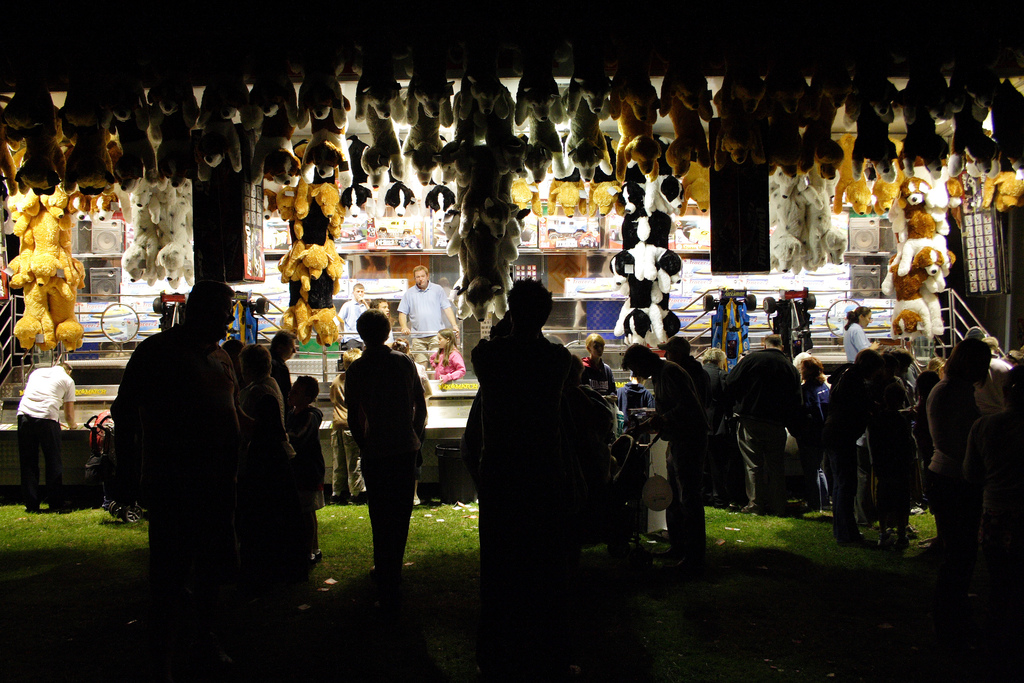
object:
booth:
[3, 9, 989, 502]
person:
[339, 309, 434, 582]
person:
[463, 264, 589, 666]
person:
[614, 340, 718, 570]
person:
[109, 268, 256, 677]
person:
[855, 346, 920, 548]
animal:
[0, 183, 92, 357]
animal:
[269, 167, 373, 348]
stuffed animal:
[889, 168, 954, 244]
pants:
[14, 413, 77, 515]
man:
[0, 357, 93, 517]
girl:
[425, 323, 472, 388]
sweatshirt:
[430, 351, 466, 386]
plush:
[618, 161, 668, 235]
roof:
[5, 1, 993, 88]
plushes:
[384, 63, 418, 218]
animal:
[607, 181, 681, 344]